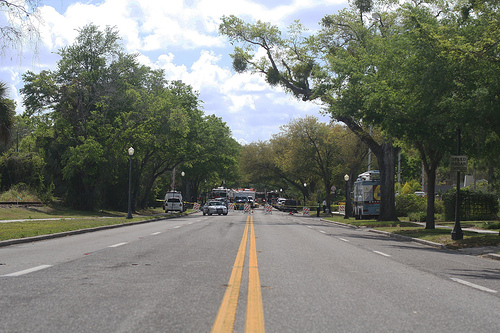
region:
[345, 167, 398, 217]
Blue and yellow food truck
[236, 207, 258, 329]
Yellow lane divider on the street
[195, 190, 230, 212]
Police car in the street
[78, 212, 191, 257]
White lines on the road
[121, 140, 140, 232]
Lamp post on the sidewalk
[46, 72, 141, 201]
Trees next to a police car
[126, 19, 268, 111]
Cloudy blue sky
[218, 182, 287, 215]
Emergency vehicle blocking street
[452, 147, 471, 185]
White sign on a pole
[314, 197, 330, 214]
Man standing next to tree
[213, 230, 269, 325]
yellow double lines in road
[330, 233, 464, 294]
white broken lines in road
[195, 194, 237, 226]
car parked in street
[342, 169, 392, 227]
truck parked on grass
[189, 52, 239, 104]
white clouds in sky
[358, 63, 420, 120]
green leaves on tree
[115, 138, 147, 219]
light on plack pole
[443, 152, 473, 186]
sign on black pole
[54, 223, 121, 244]
curb on side of street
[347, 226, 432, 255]
tree shadows on ground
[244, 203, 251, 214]
red and white barricade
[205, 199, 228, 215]
police car on street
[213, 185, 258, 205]
fire truck on street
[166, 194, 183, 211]
white van by road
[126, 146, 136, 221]
black metal street lamp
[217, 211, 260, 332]
yellow lines on road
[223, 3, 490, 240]
trees with green leaves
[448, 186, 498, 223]
hedge next to road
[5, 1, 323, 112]
white clouds in sky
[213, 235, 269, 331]
Double yellow line on a street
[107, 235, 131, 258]
Dashed white line on a street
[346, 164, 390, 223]
News van parked in grass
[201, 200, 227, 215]
Police car in the middle of the street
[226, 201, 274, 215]
Police barricade in the street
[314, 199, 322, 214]
Policeman in front of a yellow string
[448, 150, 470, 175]
Street sign on a post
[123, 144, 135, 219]
Light on a post in the grass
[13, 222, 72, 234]
Grass on the side of a road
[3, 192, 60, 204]
Train track near the road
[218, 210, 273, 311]
yellow lines in the street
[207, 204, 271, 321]
two lines side by side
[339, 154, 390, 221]
bus parked on the sidewalk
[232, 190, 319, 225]
the street is blocked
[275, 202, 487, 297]
white lines on the street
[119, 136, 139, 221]
a tall street lamp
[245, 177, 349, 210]
a row of street lights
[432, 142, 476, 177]
a black and white sign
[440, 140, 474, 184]
the letters are black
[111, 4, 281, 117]
the clouds are fluffy